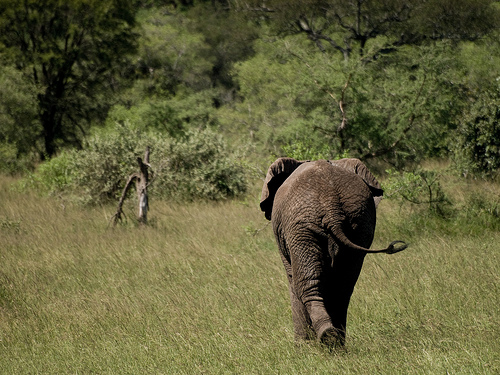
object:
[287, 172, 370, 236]
butt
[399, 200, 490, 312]
grass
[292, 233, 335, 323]
leg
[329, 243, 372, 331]
leg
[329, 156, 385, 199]
ears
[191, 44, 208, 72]
leaves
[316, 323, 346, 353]
foot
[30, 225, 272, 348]
grass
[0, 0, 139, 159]
tree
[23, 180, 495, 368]
grass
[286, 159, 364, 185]
back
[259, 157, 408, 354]
elephant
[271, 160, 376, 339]
elephant`s skin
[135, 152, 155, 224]
tree trunk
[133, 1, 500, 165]
trees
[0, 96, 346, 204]
bushes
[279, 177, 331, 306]
wrinkled skin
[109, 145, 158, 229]
stump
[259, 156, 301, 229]
ear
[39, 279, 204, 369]
ground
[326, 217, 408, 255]
tail